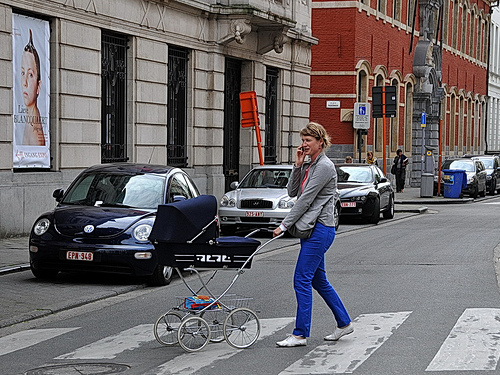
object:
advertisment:
[10, 13, 52, 168]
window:
[100, 40, 128, 162]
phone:
[299, 145, 304, 155]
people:
[362, 151, 380, 168]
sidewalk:
[395, 189, 424, 213]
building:
[310, 0, 499, 187]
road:
[311, 210, 499, 374]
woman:
[272, 121, 355, 348]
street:
[0, 238, 499, 373]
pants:
[291, 220, 352, 337]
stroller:
[147, 194, 284, 352]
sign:
[238, 91, 263, 166]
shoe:
[274, 332, 307, 347]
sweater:
[280, 151, 337, 229]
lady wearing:
[275, 150, 355, 347]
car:
[28, 146, 202, 287]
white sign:
[9, 13, 51, 169]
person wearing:
[390, 149, 410, 194]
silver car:
[218, 164, 342, 236]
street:
[351, 214, 499, 269]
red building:
[309, 0, 491, 145]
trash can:
[440, 168, 466, 198]